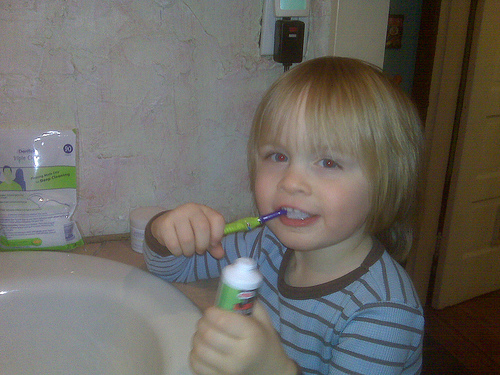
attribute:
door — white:
[425, 0, 499, 315]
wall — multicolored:
[23, 9, 377, 257]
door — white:
[431, 1, 499, 308]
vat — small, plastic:
[124, 205, 173, 256]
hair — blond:
[245, 44, 423, 239]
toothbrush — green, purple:
[223, 209, 286, 234]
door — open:
[409, 2, 498, 312]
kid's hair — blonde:
[253, 53, 423, 250]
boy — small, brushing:
[127, 44, 437, 371]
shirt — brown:
[147, 221, 429, 368]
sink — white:
[0, 249, 204, 371]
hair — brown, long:
[247, 54, 422, 216]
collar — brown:
[256, 224, 396, 297]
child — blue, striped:
[135, 60, 446, 372]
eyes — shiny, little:
[254, 143, 350, 175]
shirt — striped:
[145, 248, 424, 370]